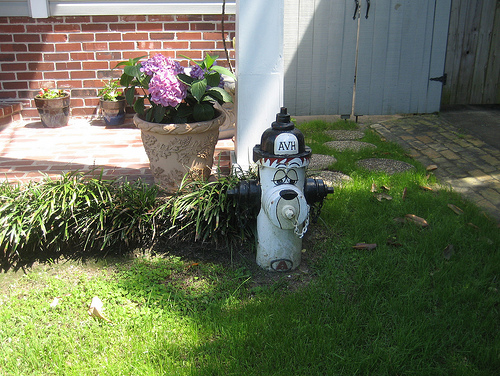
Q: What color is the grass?
A: Green.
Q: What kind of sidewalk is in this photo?
A: Brick.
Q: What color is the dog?
A: White.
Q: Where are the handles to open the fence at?
A: On the fence.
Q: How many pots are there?
A: Three.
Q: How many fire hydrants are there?
A: One.